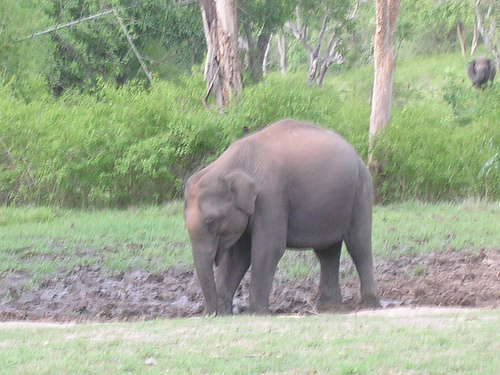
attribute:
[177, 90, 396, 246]
elephant — grazing, walking, gray, big, large, huge, mighty, alone, playing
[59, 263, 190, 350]
dirt — behind, brown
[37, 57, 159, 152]
bushes — green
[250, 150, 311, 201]
skin — wrinkled, discolored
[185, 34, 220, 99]
tree — decaying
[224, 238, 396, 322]
legs — grey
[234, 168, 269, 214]
ear — floppy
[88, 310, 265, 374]
grass — green, here, patchy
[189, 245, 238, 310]
trunk — here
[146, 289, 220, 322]
mud — here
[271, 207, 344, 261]
stomach — here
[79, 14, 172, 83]
leaves — green